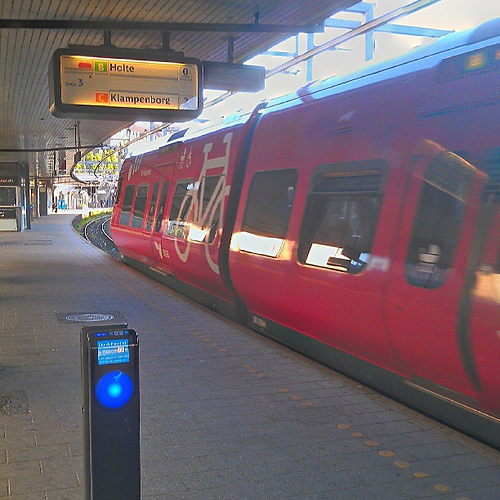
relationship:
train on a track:
[102, 12, 497, 447] [79, 205, 111, 250]